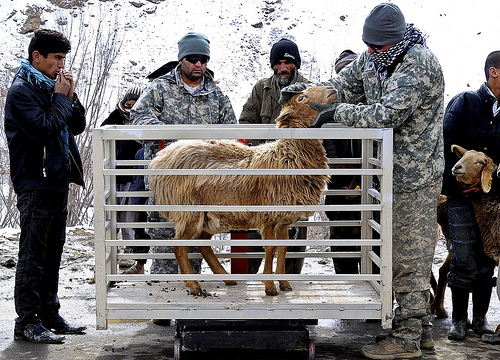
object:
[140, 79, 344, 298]
goat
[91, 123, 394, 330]
pen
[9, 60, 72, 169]
scarf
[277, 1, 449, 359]
man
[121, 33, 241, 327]
man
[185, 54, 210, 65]
sunglasses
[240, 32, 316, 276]
man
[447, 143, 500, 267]
goat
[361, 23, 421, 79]
scarf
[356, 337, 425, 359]
boot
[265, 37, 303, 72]
hat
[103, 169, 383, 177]
metal strip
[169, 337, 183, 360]
wheel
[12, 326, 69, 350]
shoe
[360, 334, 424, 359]
shoe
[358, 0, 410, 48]
cap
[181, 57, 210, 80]
face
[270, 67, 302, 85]
beard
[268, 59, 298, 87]
face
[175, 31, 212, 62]
cap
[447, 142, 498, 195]
head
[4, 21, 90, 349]
man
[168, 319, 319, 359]
cart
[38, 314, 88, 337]
shoe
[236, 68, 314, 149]
jacket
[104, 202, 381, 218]
metal strip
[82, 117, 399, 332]
cage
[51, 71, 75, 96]
hand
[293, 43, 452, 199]
jacket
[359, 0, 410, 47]
hat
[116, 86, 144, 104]
hat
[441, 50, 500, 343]
man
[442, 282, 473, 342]
boot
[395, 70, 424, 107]
camo